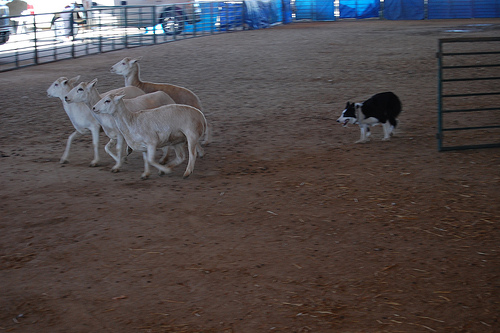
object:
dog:
[335, 92, 402, 144]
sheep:
[92, 90, 207, 179]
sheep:
[109, 57, 201, 111]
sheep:
[65, 78, 176, 173]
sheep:
[45, 75, 144, 167]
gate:
[435, 35, 500, 154]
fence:
[0, 0, 249, 74]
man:
[60, 5, 72, 38]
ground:
[0, 19, 499, 333]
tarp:
[183, 2, 500, 34]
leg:
[59, 131, 81, 163]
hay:
[315, 310, 337, 315]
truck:
[82, 0, 201, 34]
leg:
[354, 123, 366, 143]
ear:
[348, 102, 355, 109]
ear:
[345, 101, 350, 109]